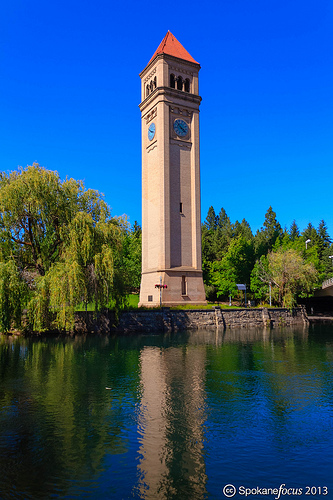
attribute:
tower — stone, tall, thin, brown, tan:
[137, 30, 211, 307]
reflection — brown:
[138, 347, 211, 499]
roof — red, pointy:
[135, 30, 201, 77]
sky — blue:
[0, 0, 331, 242]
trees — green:
[0, 163, 332, 334]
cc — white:
[223, 483, 237, 499]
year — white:
[305, 485, 329, 496]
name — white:
[240, 485, 307, 498]